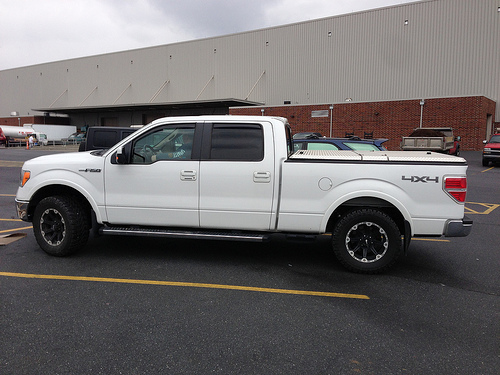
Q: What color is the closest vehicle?
A: White.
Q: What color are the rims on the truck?
A: Black.